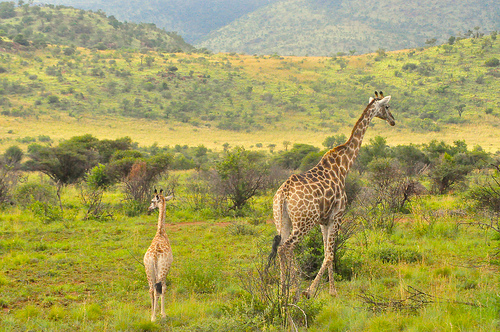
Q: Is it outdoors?
A: Yes, it is outdoors.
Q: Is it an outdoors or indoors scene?
A: It is outdoors.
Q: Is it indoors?
A: No, it is outdoors.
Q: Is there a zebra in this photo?
A: No, there are no zebras.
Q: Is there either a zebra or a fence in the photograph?
A: No, there are no zebras or fences.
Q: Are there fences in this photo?
A: No, there are no fences.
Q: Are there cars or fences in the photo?
A: No, there are no fences or cars.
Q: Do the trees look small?
A: Yes, the trees are small.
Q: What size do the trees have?
A: The trees have small size.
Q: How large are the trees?
A: The trees are small.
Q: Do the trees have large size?
A: No, the trees are small.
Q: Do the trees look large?
A: No, the trees are small.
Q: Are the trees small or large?
A: The trees are small.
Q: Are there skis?
A: No, there are no skis.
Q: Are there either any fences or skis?
A: No, there are no skis or fences.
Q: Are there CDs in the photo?
A: No, there are no cds.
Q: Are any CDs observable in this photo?
A: No, there are no cds.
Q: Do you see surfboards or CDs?
A: No, there are no CDs or surfboards.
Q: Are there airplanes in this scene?
A: No, there are no airplanes.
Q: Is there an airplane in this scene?
A: No, there are no airplanes.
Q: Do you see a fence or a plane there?
A: No, there are no airplanes or fences.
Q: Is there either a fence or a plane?
A: No, there are no airplanes or fences.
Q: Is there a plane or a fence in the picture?
A: No, there are no airplanes or fences.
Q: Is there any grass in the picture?
A: Yes, there is grass.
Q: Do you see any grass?
A: Yes, there is grass.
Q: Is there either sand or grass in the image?
A: Yes, there is grass.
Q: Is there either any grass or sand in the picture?
A: Yes, there is grass.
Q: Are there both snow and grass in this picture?
A: No, there is grass but no snow.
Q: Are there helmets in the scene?
A: No, there are no helmets.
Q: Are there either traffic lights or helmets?
A: No, there are no helmets or traffic lights.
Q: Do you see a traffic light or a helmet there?
A: No, there are no helmets or traffic lights.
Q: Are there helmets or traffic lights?
A: No, there are no helmets or traffic lights.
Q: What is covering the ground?
A: The grass is covering the ground.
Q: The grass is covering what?
A: The grass is covering the ground.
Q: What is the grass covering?
A: The grass is covering the ground.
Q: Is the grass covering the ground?
A: Yes, the grass is covering the ground.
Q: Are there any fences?
A: No, there are no fences.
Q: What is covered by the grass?
A: The ground is covered by the grass.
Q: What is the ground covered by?
A: The ground is covered by the grass.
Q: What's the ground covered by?
A: The ground is covered by the grass.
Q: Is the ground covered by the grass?
A: Yes, the ground is covered by the grass.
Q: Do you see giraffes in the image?
A: Yes, there is a giraffe.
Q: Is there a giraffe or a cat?
A: Yes, there is a giraffe.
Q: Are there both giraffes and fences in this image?
A: No, there is a giraffe but no fences.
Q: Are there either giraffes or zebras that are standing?
A: Yes, the giraffe is standing.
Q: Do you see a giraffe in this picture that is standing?
A: Yes, there is a giraffe that is standing.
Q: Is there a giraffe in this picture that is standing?
A: Yes, there is a giraffe that is standing.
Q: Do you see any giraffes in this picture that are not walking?
A: Yes, there is a giraffe that is standing .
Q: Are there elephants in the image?
A: No, there are no elephants.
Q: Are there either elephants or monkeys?
A: No, there are no elephants or monkeys.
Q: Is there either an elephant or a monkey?
A: No, there are no elephants or monkeys.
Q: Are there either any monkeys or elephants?
A: No, there are no elephants or monkeys.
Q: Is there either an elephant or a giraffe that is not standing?
A: No, there is a giraffe but it is standing.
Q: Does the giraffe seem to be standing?
A: Yes, the giraffe is standing.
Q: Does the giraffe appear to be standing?
A: Yes, the giraffe is standing.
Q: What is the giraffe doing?
A: The giraffe is standing.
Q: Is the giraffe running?
A: No, the giraffe is standing.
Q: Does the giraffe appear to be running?
A: No, the giraffe is standing.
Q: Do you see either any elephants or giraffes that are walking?
A: No, there is a giraffe but it is standing.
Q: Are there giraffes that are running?
A: No, there is a giraffe but it is standing.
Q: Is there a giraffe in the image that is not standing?
A: No, there is a giraffe but it is standing.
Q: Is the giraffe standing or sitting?
A: The giraffe is standing.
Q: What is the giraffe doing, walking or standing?
A: The giraffe is standing.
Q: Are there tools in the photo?
A: No, there are no tools.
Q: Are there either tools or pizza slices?
A: No, there are no tools or pizza slices.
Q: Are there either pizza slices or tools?
A: No, there are no tools or pizza slices.